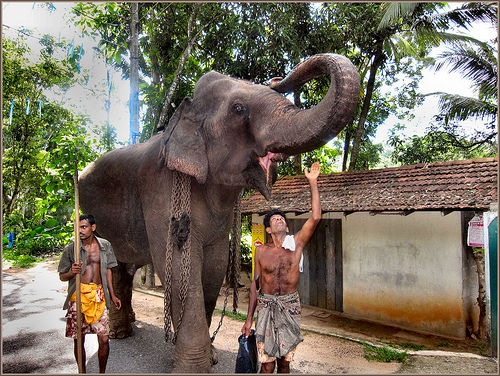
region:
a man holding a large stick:
[64, 216, 119, 369]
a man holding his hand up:
[252, 160, 324, 374]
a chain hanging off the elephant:
[155, 169, 196, 343]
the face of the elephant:
[166, 54, 361, 189]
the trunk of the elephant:
[265, 50, 361, 156]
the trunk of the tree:
[125, 25, 140, 141]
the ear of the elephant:
[159, 98, 209, 183]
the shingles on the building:
[338, 157, 496, 204]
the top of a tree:
[434, 30, 496, 125]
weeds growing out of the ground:
[359, 338, 412, 363]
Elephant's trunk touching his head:
[262, 49, 367, 163]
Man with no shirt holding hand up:
[238, 160, 328, 372]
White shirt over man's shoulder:
[279, 232, 309, 272]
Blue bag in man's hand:
[227, 328, 260, 375]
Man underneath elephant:
[234, 160, 324, 371]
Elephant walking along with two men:
[58, 49, 363, 374]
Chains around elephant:
[156, 154, 245, 351]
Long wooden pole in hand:
[70, 155, 87, 375]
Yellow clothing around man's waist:
[67, 280, 114, 324]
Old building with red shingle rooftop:
[227, 152, 498, 343]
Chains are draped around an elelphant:
[153, 134, 245, 316]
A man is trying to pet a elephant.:
[240, 150, 340, 259]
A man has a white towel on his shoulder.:
[263, 205, 333, 305]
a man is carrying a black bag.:
[226, 314, 258, 372]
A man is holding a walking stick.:
[67, 160, 137, 351]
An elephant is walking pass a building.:
[28, 83, 490, 191]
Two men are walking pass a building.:
[62, 217, 381, 361]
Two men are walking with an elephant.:
[49, 208, 382, 369]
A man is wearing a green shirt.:
[46, 239, 126, 321]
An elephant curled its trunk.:
[170, 49, 442, 190]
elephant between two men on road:
[56, 46, 364, 371]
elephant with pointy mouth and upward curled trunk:
[200, 46, 362, 201]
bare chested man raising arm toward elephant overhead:
[231, 156, 321, 366]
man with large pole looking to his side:
[50, 160, 122, 370]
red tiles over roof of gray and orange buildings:
[245, 157, 490, 347]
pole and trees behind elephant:
[125, 2, 396, 167]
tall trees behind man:
[5, 11, 125, 251]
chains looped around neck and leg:
[160, 105, 240, 362]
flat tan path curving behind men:
[0, 255, 390, 371]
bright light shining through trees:
[7, 5, 492, 161]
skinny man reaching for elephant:
[238, 157, 333, 372]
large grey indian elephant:
[67, 50, 367, 374]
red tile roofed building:
[231, 148, 498, 220]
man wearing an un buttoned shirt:
[60, 206, 128, 373]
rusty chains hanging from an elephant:
[150, 167, 250, 357]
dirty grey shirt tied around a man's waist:
[253, 288, 316, 361]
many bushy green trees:
[0, 5, 93, 282]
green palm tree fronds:
[363, 3, 498, 145]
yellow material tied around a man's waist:
[64, 274, 107, 324]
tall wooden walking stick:
[68, 148, 85, 365]